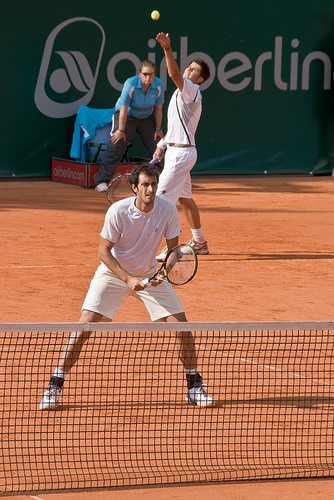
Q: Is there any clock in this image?
A: No, there are no clocks.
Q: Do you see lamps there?
A: No, there are no lamps.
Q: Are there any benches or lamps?
A: No, there are no lamps or benches.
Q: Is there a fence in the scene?
A: No, there are no fences.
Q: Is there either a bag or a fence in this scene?
A: No, there are no fences or bags.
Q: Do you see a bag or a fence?
A: No, there are no fences or bags.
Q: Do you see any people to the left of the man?
A: Yes, there is a person to the left of the man.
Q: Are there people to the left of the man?
A: Yes, there is a person to the left of the man.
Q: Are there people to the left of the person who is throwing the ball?
A: Yes, there is a person to the left of the man.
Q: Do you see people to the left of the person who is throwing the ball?
A: Yes, there is a person to the left of the man.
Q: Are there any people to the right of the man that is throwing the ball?
A: No, the person is to the left of the man.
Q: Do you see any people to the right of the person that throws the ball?
A: No, the person is to the left of the man.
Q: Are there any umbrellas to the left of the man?
A: No, there is a person to the left of the man.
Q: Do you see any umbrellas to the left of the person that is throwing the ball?
A: No, there is a person to the left of the man.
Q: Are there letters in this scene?
A: Yes, there are letters.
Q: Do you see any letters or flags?
A: Yes, there are letters.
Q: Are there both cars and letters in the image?
A: No, there are letters but no cars.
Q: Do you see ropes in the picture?
A: No, there are no ropes.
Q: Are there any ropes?
A: No, there are no ropes.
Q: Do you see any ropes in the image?
A: No, there are no ropes.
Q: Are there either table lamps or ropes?
A: No, there are no ropes or table lamps.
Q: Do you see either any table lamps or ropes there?
A: No, there are no ropes or table lamps.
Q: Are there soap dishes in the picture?
A: No, there are no soap dishes.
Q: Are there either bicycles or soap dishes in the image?
A: No, there are no soap dishes or bicycles.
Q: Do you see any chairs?
A: Yes, there is a chair.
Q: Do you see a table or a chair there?
A: Yes, there is a chair.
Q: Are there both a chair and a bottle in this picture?
A: No, there is a chair but no bottles.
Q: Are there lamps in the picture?
A: No, there are no lamps.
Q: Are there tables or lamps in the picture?
A: No, there are no lamps or tables.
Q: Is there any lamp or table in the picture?
A: No, there are no lamps or tables.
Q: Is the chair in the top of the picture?
A: Yes, the chair is in the top of the image.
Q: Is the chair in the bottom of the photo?
A: No, the chair is in the top of the image.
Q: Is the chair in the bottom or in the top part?
A: The chair is in the top of the image.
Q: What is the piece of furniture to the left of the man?
A: The piece of furniture is a chair.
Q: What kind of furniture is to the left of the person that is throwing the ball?
A: The piece of furniture is a chair.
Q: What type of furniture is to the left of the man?
A: The piece of furniture is a chair.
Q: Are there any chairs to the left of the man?
A: Yes, there is a chair to the left of the man.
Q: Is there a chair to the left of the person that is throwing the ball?
A: Yes, there is a chair to the left of the man.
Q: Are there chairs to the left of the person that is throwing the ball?
A: Yes, there is a chair to the left of the man.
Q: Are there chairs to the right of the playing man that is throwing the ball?
A: No, the chair is to the left of the man.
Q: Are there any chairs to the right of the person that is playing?
A: No, the chair is to the left of the man.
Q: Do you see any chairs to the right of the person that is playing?
A: No, the chair is to the left of the man.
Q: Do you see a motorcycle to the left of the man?
A: No, there is a chair to the left of the man.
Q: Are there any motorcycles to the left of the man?
A: No, there is a chair to the left of the man.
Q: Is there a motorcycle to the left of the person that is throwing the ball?
A: No, there is a chair to the left of the man.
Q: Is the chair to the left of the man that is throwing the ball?
A: Yes, the chair is to the left of the man.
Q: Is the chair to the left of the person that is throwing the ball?
A: Yes, the chair is to the left of the man.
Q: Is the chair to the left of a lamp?
A: No, the chair is to the left of the man.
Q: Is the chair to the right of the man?
A: No, the chair is to the left of the man.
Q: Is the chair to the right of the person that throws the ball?
A: No, the chair is to the left of the man.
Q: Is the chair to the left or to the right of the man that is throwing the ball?
A: The chair is to the left of the man.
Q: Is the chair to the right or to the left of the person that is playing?
A: The chair is to the left of the man.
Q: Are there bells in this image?
A: No, there are no bells.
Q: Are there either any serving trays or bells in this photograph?
A: No, there are no bells or serving trays.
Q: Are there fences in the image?
A: No, there are no fences.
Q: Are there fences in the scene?
A: No, there are no fences.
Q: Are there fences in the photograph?
A: No, there are no fences.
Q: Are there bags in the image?
A: No, there are no bags.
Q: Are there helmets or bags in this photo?
A: No, there are no bags or helmets.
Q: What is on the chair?
A: The jacket is on the chair.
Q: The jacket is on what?
A: The jacket is on the chair.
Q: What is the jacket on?
A: The jacket is on the chair.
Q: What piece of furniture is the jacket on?
A: The jacket is on the chair.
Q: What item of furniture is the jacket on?
A: The jacket is on the chair.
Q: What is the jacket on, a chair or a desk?
A: The jacket is on a chair.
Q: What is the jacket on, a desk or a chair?
A: The jacket is on a chair.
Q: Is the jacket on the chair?
A: Yes, the jacket is on the chair.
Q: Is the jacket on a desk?
A: No, the jacket is on the chair.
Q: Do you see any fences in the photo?
A: No, there are no fences.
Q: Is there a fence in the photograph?
A: No, there are no fences.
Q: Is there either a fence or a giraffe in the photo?
A: No, there are no fences or giraffes.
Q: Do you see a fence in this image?
A: No, there are no fences.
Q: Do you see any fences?
A: No, there are no fences.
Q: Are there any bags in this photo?
A: No, there are no bags.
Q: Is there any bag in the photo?
A: No, there are no bags.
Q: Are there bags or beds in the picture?
A: No, there are no bags or beds.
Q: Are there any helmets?
A: No, there are no helmets.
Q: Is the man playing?
A: Yes, the man is playing.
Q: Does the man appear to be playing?
A: Yes, the man is playing.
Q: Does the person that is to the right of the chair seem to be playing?
A: Yes, the man is playing.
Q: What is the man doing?
A: The man is playing.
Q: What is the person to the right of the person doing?
A: The man is playing.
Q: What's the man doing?
A: The man is playing.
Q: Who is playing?
A: The man is playing.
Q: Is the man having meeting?
A: No, the man is playing.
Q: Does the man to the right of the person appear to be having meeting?
A: No, the man is playing.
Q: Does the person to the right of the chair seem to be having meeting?
A: No, the man is playing.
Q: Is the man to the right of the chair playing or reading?
A: The man is playing.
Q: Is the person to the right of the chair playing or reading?
A: The man is playing.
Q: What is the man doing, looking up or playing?
A: The man is playing.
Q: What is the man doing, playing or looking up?
A: The man is playing.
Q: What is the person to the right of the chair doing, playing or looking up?
A: The man is playing.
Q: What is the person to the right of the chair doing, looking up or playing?
A: The man is playing.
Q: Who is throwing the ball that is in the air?
A: The man is throwing the ball.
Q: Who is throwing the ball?
A: The man is throwing the ball.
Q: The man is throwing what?
A: The man is throwing the ball.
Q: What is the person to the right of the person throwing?
A: The man is throwing the ball.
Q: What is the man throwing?
A: The man is throwing the ball.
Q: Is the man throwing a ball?
A: Yes, the man is throwing a ball.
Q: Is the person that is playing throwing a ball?
A: Yes, the man is throwing a ball.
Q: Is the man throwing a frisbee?
A: No, the man is throwing a ball.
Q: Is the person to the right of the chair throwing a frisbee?
A: No, the man is throwing a ball.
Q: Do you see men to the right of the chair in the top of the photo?
A: Yes, there is a man to the right of the chair.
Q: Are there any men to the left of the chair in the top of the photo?
A: No, the man is to the right of the chair.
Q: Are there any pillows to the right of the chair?
A: No, there is a man to the right of the chair.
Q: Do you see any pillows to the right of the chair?
A: No, there is a man to the right of the chair.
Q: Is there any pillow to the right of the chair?
A: No, there is a man to the right of the chair.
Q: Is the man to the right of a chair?
A: Yes, the man is to the right of a chair.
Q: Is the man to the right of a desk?
A: No, the man is to the right of a chair.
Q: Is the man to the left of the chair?
A: No, the man is to the right of the chair.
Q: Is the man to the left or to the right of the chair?
A: The man is to the right of the chair.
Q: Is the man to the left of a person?
A: No, the man is to the right of a person.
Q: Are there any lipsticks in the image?
A: No, there are no lipsticks.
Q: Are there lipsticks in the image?
A: No, there are no lipsticks.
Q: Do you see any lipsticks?
A: No, there are no lipsticks.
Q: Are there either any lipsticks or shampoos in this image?
A: No, there are no lipsticks or shampoos.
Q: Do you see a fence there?
A: No, there are no fences.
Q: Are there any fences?
A: No, there are no fences.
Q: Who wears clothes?
A: The player wears clothes.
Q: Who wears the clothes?
A: The player wears clothes.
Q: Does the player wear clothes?
A: Yes, the player wears clothes.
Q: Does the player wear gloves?
A: No, the player wears clothes.